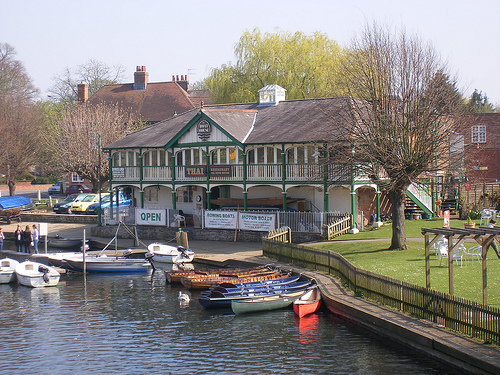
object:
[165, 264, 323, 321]
boats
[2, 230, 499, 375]
wall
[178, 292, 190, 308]
bird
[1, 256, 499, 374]
water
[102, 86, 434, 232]
building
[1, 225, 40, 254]
people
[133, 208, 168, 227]
sign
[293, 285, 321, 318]
boat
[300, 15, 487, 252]
tree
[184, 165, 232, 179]
sign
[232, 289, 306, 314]
canoe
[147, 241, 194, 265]
motorboat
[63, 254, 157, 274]
motoboat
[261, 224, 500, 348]
fence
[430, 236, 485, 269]
chairs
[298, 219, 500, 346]
lawn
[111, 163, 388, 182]
balcony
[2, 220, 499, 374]
sidewalk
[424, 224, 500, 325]
gazebo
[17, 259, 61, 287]
boat